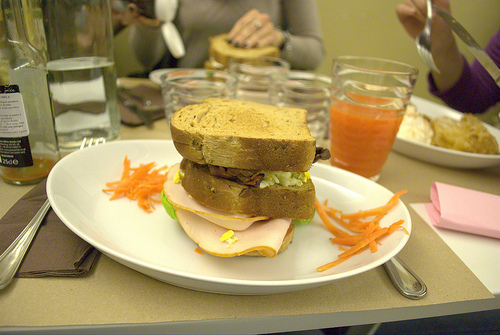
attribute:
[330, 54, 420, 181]
glass — clear, round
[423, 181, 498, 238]
paper — pink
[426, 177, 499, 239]
paper — pink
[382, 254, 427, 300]
handle — silver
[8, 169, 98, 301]
napkin — brown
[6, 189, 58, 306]
fork — silver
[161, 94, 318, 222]
bread — brown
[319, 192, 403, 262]
carrots — shredded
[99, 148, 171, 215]
carrots — shredded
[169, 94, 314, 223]
sandwich — brown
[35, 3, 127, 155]
pitcher — clear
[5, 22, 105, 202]
bottle — empty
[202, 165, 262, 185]
roast beef — real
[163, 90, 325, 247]
sandwich — served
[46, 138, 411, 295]
plate — white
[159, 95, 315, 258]
cold cut — turkey, tofurky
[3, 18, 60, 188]
bottle — empty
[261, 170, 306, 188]
shredded lettuce — green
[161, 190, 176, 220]
shredded lettuce — green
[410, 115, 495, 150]
food — served